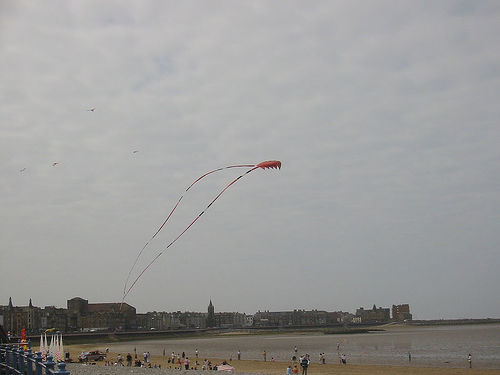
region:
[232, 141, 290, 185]
kite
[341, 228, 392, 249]
white clouds in blue sky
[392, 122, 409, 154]
white clouds in blue sky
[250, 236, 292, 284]
white clouds in blue sky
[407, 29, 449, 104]
white clouds in blue sky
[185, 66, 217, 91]
white clouds in blue sky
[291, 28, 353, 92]
white clouds in blue sky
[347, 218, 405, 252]
white clouds in blue sky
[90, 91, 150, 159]
white clouds in blue sky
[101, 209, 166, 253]
white clouds in blue sky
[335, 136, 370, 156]
white clouds in blue sky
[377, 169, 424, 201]
white clouds in blue sky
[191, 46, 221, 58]
white clouds in blue sky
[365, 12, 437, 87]
white clouds in blue sky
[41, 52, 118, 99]
white clouds in blue sky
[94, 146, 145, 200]
white clouds in blue sky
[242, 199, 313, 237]
white clouds in blue sky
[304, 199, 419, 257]
white clouds in blue sky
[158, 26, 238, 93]
white clouds in blue sky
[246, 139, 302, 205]
a kite in the sky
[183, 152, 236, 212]
two tails of a kite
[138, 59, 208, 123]
wispy clouds up in the sky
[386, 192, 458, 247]
the blue of the sky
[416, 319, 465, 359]
the calm waters of the ocean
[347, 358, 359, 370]
a bunch of sand on the coast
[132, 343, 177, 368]
a bunch of tourists on the beach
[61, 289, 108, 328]
a tall brown apartment building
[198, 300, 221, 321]
a big grey tower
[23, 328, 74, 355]
a big white fountain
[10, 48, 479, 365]
A big orange kite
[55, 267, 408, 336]
A seaside city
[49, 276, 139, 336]
A large building on water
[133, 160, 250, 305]
Tail hanging from kite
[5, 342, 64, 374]
A cement railing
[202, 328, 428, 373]
A beach front area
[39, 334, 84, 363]
Tall white decorations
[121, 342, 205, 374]
A crowd of people on the beach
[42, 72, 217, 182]
Birds flying in the sky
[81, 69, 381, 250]
A hazy looking sky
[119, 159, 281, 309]
Red kite with two tails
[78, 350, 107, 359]
automobile on the sand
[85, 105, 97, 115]
bird flying in the sky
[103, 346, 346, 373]
people standing on a beach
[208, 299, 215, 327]
tall building near the sea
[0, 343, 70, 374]
Poled railing near the beach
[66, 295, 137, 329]
Large brown building near sea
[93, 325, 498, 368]
water on the edge of a beach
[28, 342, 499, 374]
Sand on the beach